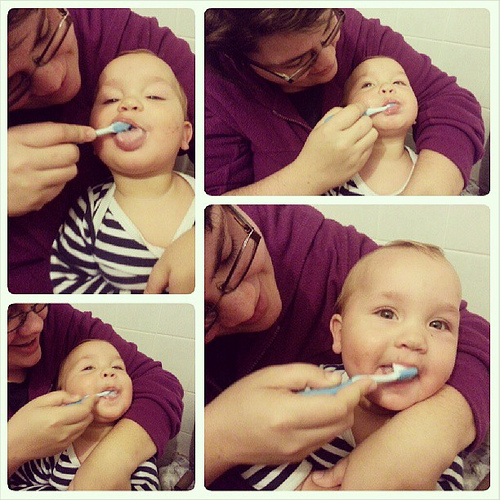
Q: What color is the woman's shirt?
A: Purple.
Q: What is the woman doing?
A: Brushing the boys teeth.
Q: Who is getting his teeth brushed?
A: The boy.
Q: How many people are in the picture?
A: 2.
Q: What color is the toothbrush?
A: White.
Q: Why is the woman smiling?
A: She is happy.